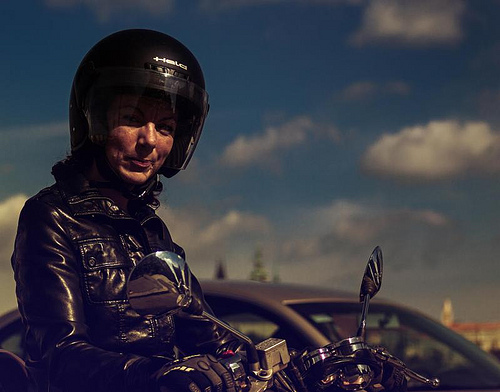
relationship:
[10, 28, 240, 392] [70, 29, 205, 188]
bike rider has head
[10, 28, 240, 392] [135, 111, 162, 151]
bike rider has nose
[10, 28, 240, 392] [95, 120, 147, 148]
bike rider has cheek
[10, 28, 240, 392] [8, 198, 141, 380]
bike rider has arm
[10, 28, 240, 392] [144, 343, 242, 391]
bike rider has hand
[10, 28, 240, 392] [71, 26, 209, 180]
bike rider wears helmet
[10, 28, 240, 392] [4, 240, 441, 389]
bike rider on bike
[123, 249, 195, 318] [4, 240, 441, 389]
mirror on bike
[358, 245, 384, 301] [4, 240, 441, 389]
mirror on bike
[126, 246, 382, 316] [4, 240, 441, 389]
mirror on bike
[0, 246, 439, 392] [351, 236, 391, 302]
bike has mirror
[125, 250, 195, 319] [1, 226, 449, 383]
mirror on bike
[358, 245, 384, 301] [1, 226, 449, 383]
mirror on bike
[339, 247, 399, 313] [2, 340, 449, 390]
mirror on bike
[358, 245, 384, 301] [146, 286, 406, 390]
mirror on bike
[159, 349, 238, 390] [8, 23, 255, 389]
glove on bike rider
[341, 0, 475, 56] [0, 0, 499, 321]
clouds in sky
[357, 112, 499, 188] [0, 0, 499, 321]
clouds in sky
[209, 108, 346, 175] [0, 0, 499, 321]
clouds in sky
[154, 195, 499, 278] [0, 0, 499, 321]
clouds in sky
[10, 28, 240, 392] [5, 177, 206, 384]
bike rider wears jacket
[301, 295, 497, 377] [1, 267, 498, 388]
windshield on car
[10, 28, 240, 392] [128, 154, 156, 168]
bike rider has lips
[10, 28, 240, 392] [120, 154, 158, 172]
bike rider has lips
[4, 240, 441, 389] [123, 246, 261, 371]
bike has mirror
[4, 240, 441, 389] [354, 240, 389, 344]
bike has mirror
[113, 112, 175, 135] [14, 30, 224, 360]
eyes of woman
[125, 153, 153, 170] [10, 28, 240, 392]
lips on bike rider